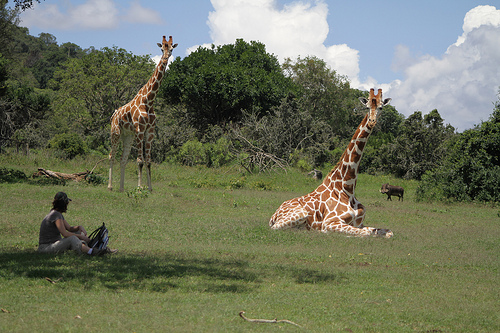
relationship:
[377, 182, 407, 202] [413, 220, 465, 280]
boar standing field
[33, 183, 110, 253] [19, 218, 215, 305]
man sitting ground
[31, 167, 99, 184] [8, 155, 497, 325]
dead tree lying ground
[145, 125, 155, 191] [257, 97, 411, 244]
leg lying giraffe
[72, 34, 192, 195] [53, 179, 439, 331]
giraffe standing field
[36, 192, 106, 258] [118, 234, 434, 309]
man sitting grass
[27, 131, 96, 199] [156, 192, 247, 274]
wood on ground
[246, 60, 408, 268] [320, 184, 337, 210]
giraffe has spot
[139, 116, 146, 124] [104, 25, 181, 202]
brown spot on giraffe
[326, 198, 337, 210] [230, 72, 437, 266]
brown spot on giraffe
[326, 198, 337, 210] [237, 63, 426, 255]
brown spot on giraffe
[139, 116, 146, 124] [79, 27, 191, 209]
brown spot on giraffe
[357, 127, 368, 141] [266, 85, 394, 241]
spot on giraffe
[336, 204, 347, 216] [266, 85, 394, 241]
spot on giraffe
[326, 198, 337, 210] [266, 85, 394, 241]
brown spot on giraffe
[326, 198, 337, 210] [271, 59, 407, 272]
brown spot on giraffe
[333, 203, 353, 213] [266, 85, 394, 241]
spot on giraffe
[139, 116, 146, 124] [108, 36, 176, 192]
brown spot on giraffe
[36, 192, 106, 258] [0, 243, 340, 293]
man sitting in shade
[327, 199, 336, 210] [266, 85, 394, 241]
brown spot on giraffe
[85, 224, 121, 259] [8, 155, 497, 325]
backpack on ground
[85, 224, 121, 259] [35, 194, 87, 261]
backpack in front of a man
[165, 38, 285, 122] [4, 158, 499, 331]
tree in a field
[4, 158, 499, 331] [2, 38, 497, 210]
field in a vegetation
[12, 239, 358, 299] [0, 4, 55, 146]
shadow of a tree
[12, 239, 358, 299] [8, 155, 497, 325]
shadow on ground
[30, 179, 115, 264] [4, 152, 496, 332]
woman sitting in grass